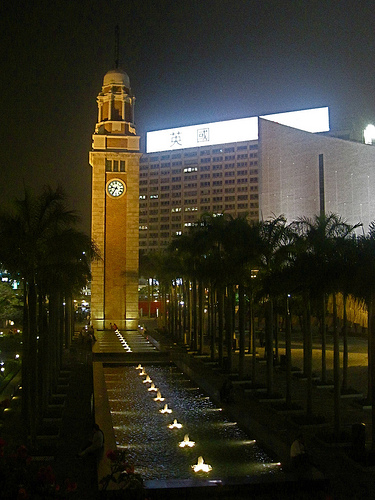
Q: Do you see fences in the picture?
A: No, there are no fences.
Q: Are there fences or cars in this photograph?
A: No, there are no fences or cars.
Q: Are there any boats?
A: No, there are no boats.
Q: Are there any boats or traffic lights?
A: No, there are no boats or traffic lights.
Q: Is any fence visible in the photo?
A: No, there are no fences.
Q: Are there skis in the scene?
A: No, there are no skis.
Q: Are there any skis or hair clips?
A: No, there are no skis or hair clips.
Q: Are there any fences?
A: No, there are no fences.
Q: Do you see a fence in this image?
A: No, there are no fences.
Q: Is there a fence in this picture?
A: No, there are no fences.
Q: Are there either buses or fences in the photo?
A: No, there are no fences or buses.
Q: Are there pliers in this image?
A: No, there are no pliers.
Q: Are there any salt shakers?
A: No, there are no salt shakers.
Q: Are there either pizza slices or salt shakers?
A: No, there are no salt shakers or pizza slices.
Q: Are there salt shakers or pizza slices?
A: No, there are no salt shakers or pizza slices.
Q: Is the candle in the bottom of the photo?
A: Yes, the candle is in the bottom of the image.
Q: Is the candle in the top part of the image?
A: No, the candle is in the bottom of the image.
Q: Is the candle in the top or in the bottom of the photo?
A: The candle is in the bottom of the image.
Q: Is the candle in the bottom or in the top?
A: The candle is in the bottom of the image.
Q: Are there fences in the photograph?
A: No, there are no fences.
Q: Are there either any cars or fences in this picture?
A: No, there are no fences or cars.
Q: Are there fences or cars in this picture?
A: No, there are no fences or cars.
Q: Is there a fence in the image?
A: No, there are no fences.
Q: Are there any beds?
A: No, there are no beds.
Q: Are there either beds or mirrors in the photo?
A: No, there are no beds or mirrors.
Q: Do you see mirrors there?
A: No, there are no mirrors.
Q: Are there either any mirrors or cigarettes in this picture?
A: No, there are no mirrors or cigarettes.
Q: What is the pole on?
A: The pole is on the building.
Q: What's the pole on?
A: The pole is on the building.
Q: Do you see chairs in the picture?
A: No, there are no chairs.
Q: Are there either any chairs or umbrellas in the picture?
A: No, there are no chairs or umbrellas.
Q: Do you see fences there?
A: No, there are no fences.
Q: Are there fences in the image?
A: No, there are no fences.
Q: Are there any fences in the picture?
A: No, there are no fences.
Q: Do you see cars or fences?
A: No, there are no fences or cars.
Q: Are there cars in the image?
A: No, there are no cars.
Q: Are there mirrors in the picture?
A: No, there are no mirrors.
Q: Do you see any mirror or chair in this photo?
A: No, there are no mirrors or chairs.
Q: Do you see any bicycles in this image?
A: No, there are no bicycles.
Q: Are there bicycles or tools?
A: No, there are no bicycles or tools.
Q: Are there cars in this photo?
A: No, there are no cars.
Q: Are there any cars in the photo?
A: No, there are no cars.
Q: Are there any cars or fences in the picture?
A: No, there are no cars or fences.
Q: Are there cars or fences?
A: No, there are no fences or cars.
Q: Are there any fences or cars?
A: No, there are no fences or cars.